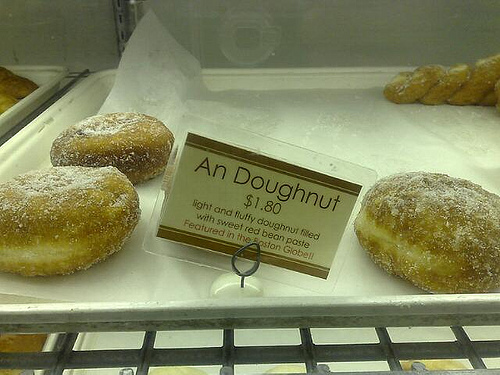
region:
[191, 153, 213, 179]
The letter is brown.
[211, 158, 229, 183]
The letter is brown.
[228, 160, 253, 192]
The letter is brown.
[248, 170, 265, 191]
The letter is brown.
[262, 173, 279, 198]
The letter is brown.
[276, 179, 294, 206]
The letter is brown.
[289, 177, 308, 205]
The letter is brown.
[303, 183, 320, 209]
The letter is brown.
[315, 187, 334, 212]
The letter is brown.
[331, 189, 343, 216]
The letter is brown.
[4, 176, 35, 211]
powder sugar on donut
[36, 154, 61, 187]
powder sugar on donut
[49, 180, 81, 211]
powder sugar on donut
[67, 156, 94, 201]
powder sugar on donut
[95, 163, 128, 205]
powder sugar on donut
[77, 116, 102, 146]
powder sugar on donut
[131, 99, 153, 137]
powder sugar on donut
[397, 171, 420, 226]
powder sugar on donut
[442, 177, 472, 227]
powder sugar on donut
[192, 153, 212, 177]
black letter on sign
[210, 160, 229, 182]
black letter on sign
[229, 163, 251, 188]
black letter on sign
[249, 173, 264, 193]
black letter on sign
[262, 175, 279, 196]
black letter on sign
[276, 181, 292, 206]
black letter on sign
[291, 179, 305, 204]
black letter on sign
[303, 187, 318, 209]
black letter on sign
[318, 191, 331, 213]
black letter on sign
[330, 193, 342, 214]
black letter on sign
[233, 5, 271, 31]
this is the wall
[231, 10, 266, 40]
the wall is white in color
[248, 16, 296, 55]
the wall is clean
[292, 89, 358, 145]
this is a tray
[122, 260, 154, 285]
the tray is white in color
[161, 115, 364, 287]
this is a price tag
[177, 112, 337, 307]
the tag is big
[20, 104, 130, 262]
these are two doughnuts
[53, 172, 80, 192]
the sprinkles are white in color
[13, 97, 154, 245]
trhe donuts have wwhite topings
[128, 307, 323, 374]
the tray is on a stand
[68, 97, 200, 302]
donuts are on a polythene paper in a tray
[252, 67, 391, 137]
the tray is white in color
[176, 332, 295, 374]
the stand is made of metal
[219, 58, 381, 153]
the tray is white in color